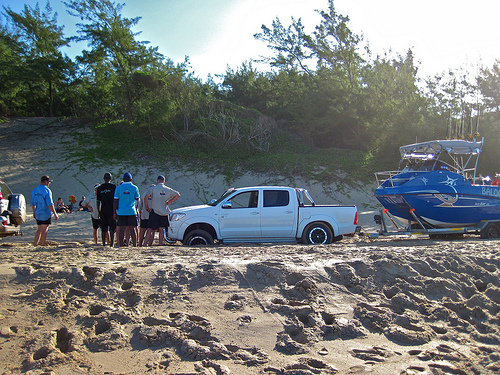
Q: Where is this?
A: This is at the beach.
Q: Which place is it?
A: It is a beach.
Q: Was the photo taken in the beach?
A: Yes, it was taken in the beach.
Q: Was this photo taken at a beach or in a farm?
A: It was taken at a beach.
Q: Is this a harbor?
A: No, it is a beach.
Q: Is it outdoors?
A: Yes, it is outdoors.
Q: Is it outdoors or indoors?
A: It is outdoors.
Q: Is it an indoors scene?
A: No, it is outdoors.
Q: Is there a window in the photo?
A: Yes, there is a window.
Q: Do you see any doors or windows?
A: Yes, there is a window.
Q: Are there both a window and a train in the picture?
A: No, there is a window but no trains.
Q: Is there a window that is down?
A: Yes, there is a window that is down.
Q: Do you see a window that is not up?
A: Yes, there is a window that is down .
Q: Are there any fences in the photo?
A: No, there are no fences.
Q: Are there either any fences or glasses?
A: No, there are no fences or glasses.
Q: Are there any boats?
A: Yes, there is a boat.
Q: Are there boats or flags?
A: Yes, there is a boat.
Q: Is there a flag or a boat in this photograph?
A: Yes, there is a boat.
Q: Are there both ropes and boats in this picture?
A: No, there is a boat but no ropes.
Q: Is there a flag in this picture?
A: No, there are no flags.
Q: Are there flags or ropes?
A: No, there are no flags or ropes.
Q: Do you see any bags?
A: No, there are no bags.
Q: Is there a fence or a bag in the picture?
A: No, there are no bags or fences.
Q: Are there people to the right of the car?
A: Yes, there are people to the right of the car.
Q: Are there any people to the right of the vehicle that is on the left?
A: Yes, there are people to the right of the car.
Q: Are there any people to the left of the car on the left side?
A: No, the people are to the right of the car.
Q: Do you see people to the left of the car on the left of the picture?
A: No, the people are to the right of the car.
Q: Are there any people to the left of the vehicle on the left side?
A: No, the people are to the right of the car.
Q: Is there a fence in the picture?
A: No, there are no fences.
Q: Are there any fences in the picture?
A: No, there are no fences.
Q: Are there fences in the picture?
A: No, there are no fences.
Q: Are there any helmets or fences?
A: No, there are no fences or helmets.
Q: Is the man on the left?
A: Yes, the man is on the left of the image.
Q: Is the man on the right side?
A: No, the man is on the left of the image.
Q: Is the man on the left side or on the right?
A: The man is on the left of the image.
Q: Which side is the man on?
A: The man is on the left of the image.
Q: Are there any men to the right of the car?
A: Yes, there is a man to the right of the car.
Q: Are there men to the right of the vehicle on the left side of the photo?
A: Yes, there is a man to the right of the car.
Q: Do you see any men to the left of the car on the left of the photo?
A: No, the man is to the right of the car.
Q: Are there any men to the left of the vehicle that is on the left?
A: No, the man is to the right of the car.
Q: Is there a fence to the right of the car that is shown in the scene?
A: No, there is a man to the right of the car.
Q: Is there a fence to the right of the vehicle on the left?
A: No, there is a man to the right of the car.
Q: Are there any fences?
A: No, there are no fences.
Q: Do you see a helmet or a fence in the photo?
A: No, there are no fences or helmets.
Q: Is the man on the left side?
A: Yes, the man is on the left of the image.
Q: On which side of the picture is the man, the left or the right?
A: The man is on the left of the image.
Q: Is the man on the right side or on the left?
A: The man is on the left of the image.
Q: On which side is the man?
A: The man is on the left of the image.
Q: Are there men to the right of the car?
A: Yes, there is a man to the right of the car.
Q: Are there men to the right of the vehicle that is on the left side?
A: Yes, there is a man to the right of the car.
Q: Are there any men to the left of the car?
A: No, the man is to the right of the car.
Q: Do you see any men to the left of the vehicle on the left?
A: No, the man is to the right of the car.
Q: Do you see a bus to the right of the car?
A: No, there is a man to the right of the car.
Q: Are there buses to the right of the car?
A: No, there is a man to the right of the car.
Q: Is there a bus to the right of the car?
A: No, there is a man to the right of the car.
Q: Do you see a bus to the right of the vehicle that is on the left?
A: No, there is a man to the right of the car.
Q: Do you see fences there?
A: No, there are no fences.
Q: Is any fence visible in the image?
A: No, there are no fences.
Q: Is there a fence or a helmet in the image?
A: No, there are no fences or helmets.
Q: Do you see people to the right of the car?
A: Yes, there is a person to the right of the car.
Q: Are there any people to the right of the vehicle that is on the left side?
A: Yes, there is a person to the right of the car.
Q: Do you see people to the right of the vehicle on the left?
A: Yes, there is a person to the right of the car.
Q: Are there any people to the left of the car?
A: No, the person is to the right of the car.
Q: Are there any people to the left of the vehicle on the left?
A: No, the person is to the right of the car.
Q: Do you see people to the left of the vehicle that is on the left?
A: No, the person is to the right of the car.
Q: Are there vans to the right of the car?
A: No, there is a person to the right of the car.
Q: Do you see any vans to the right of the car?
A: No, there is a person to the right of the car.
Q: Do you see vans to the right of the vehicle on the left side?
A: No, there is a person to the right of the car.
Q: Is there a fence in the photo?
A: No, there are no fences.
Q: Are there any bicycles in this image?
A: No, there are no bicycles.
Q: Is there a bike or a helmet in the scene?
A: No, there are no bikes or helmets.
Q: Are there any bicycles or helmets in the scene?
A: No, there are no bicycles or helmets.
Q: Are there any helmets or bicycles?
A: No, there are no bicycles or helmets.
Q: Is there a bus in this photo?
A: No, there are no buses.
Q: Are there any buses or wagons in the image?
A: No, there are no buses or wagons.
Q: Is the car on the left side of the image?
A: Yes, the car is on the left of the image.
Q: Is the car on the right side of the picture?
A: No, the car is on the left of the image.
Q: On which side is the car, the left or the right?
A: The car is on the left of the image.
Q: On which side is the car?
A: The car is on the left of the image.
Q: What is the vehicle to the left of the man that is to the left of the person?
A: The vehicle is a car.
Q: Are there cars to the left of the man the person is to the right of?
A: Yes, there is a car to the left of the man.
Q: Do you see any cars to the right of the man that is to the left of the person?
A: No, the car is to the left of the man.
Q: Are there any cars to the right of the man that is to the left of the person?
A: No, the car is to the left of the man.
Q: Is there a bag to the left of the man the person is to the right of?
A: No, there is a car to the left of the man.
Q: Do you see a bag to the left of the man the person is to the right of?
A: No, there is a car to the left of the man.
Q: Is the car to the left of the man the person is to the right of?
A: Yes, the car is to the left of the man.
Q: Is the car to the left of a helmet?
A: No, the car is to the left of the man.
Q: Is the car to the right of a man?
A: No, the car is to the left of a man.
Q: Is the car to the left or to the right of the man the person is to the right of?
A: The car is to the left of the man.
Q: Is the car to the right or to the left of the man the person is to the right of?
A: The car is to the left of the man.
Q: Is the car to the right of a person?
A: No, the car is to the left of a person.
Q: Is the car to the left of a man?
A: Yes, the car is to the left of a man.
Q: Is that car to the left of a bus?
A: No, the car is to the left of a man.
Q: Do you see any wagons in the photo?
A: No, there are no wagons.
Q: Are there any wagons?
A: No, there are no wagons.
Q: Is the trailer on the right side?
A: Yes, the trailer is on the right of the image.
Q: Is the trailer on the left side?
A: No, the trailer is on the right of the image.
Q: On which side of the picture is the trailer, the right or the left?
A: The trailer is on the right of the image.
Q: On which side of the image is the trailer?
A: The trailer is on the right of the image.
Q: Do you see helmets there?
A: No, there are no helmets.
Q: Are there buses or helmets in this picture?
A: No, there are no helmets or buses.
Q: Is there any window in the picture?
A: Yes, there is a window.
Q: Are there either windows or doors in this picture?
A: Yes, there is a window.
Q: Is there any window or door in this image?
A: Yes, there is a window.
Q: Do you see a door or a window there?
A: Yes, there is a window.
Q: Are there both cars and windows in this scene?
A: Yes, there are both a window and a car.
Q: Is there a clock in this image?
A: No, there are no clocks.